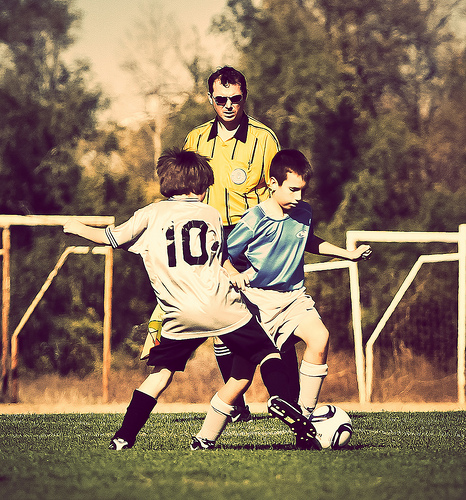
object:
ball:
[307, 404, 353, 449]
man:
[180, 64, 281, 424]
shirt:
[183, 111, 281, 227]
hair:
[208, 65, 248, 100]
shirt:
[104, 196, 253, 341]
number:
[165, 219, 208, 268]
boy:
[189, 149, 371, 454]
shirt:
[226, 199, 315, 292]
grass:
[0, 412, 466, 497]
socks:
[197, 393, 237, 442]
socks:
[113, 388, 157, 442]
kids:
[62, 147, 317, 449]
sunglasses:
[211, 94, 243, 104]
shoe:
[266, 395, 318, 441]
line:
[354, 426, 465, 438]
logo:
[229, 168, 248, 185]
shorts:
[243, 287, 320, 352]